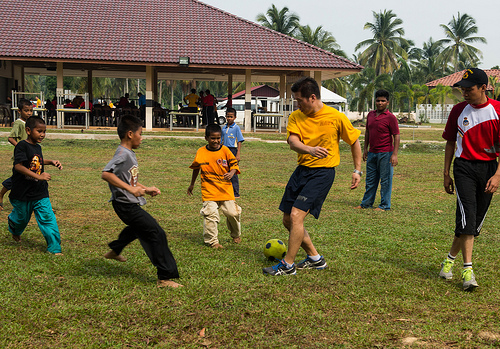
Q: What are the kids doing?
A: Playing.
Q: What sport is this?
A: Soccer.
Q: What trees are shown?
A: Palm.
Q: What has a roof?
A: The building.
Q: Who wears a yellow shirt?
A: The man.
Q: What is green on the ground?
A: Grass.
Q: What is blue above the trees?
A: Sky.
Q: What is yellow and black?
A: The ball.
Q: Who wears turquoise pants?
A: The little boy.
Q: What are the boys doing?
A: They are playing soccer.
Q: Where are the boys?
A: They are at a park.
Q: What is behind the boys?
A: A pavilion.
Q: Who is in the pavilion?
A: A group of people.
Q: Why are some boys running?
A: They are trying to kick the ball.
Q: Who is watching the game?
A: A man in a red shirt.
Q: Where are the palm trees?
A: Behind the pavilion.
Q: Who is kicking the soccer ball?
A: The man in the yellow shirt.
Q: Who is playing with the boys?
A: Two men.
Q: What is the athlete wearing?
A: A yellow shirt.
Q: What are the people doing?
A: Playing soccer.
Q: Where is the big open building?
A: Behind the people.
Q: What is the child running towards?
A: The soccer ball.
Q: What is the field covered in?
A: Grass.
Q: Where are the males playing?
A: In a field.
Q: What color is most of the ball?
A: Yellow.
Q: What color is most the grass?
A: Green.